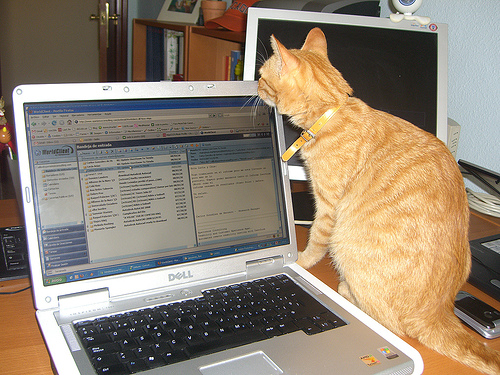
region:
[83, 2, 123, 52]
a door's golden handle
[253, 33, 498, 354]
a red tabby cat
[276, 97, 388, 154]
a yellow cat collar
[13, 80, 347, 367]
a laptop with its lid open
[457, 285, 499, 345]
a black and silvery phone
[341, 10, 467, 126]
a computer monitor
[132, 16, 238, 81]
two bookshelves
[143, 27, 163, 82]
two blue books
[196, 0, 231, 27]
a brown flower pot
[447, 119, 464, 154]
the tip of a white modem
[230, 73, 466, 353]
The cat is sitting next to the laptop.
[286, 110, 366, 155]
The cat is wearing a collar.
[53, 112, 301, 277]
The laptop is turned on.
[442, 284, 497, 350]
The cellphone is on the table.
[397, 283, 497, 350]
The cellphone is by the cat's tail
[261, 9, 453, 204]
The monitor is turned off.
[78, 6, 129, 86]
The wooden door is open.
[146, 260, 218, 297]
The laptop brand is "Dell"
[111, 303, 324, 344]
The keyboard on the laptop is black.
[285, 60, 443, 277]
The cat is a brownish color.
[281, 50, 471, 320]
brown tabby cat on table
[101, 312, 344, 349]
black and white laptop keyboard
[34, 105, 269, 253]
lit laptop screen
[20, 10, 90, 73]
white door of room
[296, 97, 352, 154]
yellow collar on cat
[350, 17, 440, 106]
screen on monitor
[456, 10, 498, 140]
white colored wall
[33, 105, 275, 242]
blue, gray and white software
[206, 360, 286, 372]
silver touch pad of laptop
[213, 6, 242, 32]
orange cap on shelf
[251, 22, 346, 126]
the head of a cat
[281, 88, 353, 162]
a yellow collar on the cat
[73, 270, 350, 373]
a black computer keyboard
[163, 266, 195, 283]
silver writing on the laptop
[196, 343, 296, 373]
a gray laptop touch pad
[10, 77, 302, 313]
a gray laptop monitor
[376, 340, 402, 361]
a sticker on the laptop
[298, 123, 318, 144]
a buckle on the collar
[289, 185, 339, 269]
the leg of a cat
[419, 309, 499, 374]
the tail of a cat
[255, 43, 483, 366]
a orange cat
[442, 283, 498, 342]
a black and grey cellphone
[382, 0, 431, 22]
a webcam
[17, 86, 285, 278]
a laptop screen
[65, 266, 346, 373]
a black laptop keyboard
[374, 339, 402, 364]
windows logo on laptop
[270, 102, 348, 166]
a orange pet collar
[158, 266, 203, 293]
company logo on a laptop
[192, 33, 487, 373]
a orange cat looking at laptop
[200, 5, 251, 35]
red visor hat on shelf